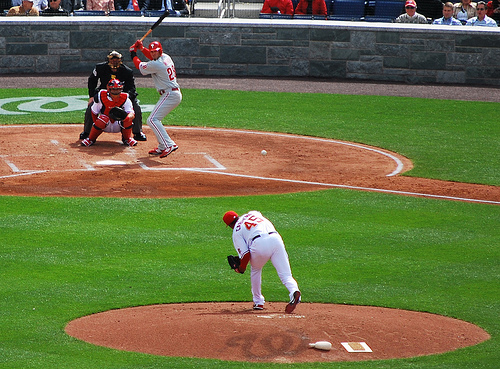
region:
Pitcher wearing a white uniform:
[213, 200, 309, 324]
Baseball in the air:
[251, 138, 275, 166]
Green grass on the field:
[339, 205, 454, 285]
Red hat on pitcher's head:
[215, 205, 249, 234]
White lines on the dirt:
[192, 138, 258, 192]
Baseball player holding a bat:
[124, 7, 187, 162]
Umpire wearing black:
[87, 51, 140, 95]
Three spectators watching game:
[396, 0, 498, 37]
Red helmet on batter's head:
[139, 32, 171, 62]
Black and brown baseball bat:
[130, 7, 171, 58]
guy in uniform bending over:
[207, 195, 319, 317]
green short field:
[232, 94, 366, 126]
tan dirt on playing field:
[137, 295, 465, 318]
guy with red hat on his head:
[219, 208, 238, 228]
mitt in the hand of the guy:
[227, 252, 239, 276]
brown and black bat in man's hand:
[130, 15, 171, 37]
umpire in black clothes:
[90, 46, 135, 74]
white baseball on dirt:
[257, 138, 272, 160]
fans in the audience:
[387, 17, 499, 32]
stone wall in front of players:
[189, 30, 491, 87]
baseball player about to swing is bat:
[131, 8, 194, 163]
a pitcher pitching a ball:
[213, 192, 320, 322]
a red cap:
[221, 205, 243, 225]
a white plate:
[338, 324, 370, 366]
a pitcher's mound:
[88, 299, 440, 366]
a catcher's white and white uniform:
[86, 90, 141, 149]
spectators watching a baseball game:
[265, 1, 495, 29]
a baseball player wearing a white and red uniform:
[132, 41, 189, 156]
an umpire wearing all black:
[91, 50, 131, 79]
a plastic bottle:
[304, 335, 334, 349]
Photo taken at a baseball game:
[20, 0, 487, 362]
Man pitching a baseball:
[216, 194, 308, 309]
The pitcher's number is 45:
[204, 191, 322, 317]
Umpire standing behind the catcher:
[75, 41, 150, 138]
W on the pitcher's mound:
[213, 321, 327, 364]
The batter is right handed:
[127, 18, 207, 169]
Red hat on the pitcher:
[220, 206, 246, 230]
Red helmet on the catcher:
[142, 36, 169, 61]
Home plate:
[84, 138, 144, 170]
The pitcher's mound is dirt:
[35, 287, 492, 353]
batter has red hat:
[143, 42, 163, 59]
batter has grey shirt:
[148, 53, 164, 88]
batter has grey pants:
[156, 89, 183, 144]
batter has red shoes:
[152, 139, 180, 162]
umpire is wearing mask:
[103, 53, 131, 66]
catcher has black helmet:
[107, 79, 135, 96]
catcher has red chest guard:
[91, 92, 134, 127]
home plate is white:
[90, 156, 134, 176]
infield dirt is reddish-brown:
[71, 141, 256, 223]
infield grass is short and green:
[80, 146, 249, 267]